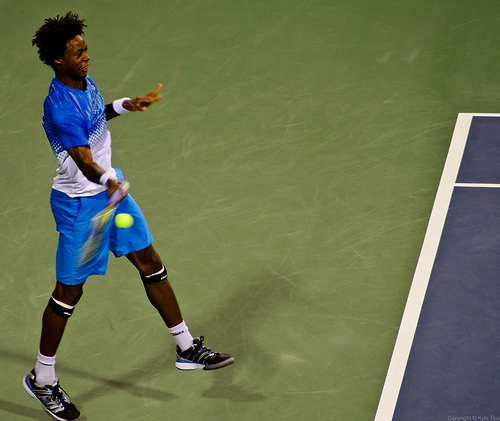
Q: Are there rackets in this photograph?
A: Yes, there is a racket.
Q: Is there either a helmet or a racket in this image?
A: Yes, there is a racket.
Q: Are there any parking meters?
A: No, there are no parking meters.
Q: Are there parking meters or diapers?
A: No, there are no parking meters or diapers.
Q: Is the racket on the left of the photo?
A: Yes, the racket is on the left of the image.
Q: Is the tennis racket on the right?
A: No, the tennis racket is on the left of the image.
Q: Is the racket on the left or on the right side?
A: The racket is on the left of the image.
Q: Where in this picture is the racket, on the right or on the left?
A: The racket is on the left of the image.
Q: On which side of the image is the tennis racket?
A: The tennis racket is on the left of the image.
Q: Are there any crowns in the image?
A: No, there are no crowns.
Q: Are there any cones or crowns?
A: No, there are no crowns or cones.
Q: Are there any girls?
A: No, there are no girls.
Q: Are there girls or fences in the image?
A: No, there are no girls or fences.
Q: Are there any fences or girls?
A: No, there are no girls or fences.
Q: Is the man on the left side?
A: Yes, the man is on the left of the image.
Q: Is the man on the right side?
A: No, the man is on the left of the image.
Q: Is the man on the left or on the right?
A: The man is on the left of the image.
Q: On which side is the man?
A: The man is on the left of the image.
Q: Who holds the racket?
A: The man holds the racket.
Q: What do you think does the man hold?
A: The man holds the tennis racket.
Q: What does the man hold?
A: The man holds the tennis racket.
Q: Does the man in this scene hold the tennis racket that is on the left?
A: Yes, the man holds the tennis racket.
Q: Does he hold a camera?
A: No, the man holds the tennis racket.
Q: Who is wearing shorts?
A: The man is wearing shorts.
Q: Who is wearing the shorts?
A: The man is wearing shorts.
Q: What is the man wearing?
A: The man is wearing shorts.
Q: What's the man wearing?
A: The man is wearing shorts.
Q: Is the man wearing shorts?
A: Yes, the man is wearing shorts.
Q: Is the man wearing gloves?
A: No, the man is wearing shorts.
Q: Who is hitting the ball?
A: The man is hitting the ball.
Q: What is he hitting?
A: The man is hitting the ball.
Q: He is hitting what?
A: The man is hitting the ball.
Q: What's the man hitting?
A: The man is hitting the ball.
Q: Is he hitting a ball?
A: Yes, the man is hitting a ball.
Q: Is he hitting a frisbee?
A: No, the man is hitting a ball.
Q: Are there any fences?
A: No, there are no fences.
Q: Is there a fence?
A: No, there are no fences.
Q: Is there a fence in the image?
A: No, there are no fences.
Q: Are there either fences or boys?
A: No, there are no fences or boys.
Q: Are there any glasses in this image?
A: No, there are no glasses.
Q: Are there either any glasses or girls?
A: No, there are no glasses or girls.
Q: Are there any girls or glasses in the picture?
A: No, there are no glasses or girls.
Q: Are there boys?
A: No, there are no boys.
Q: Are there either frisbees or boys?
A: No, there are no boys or frisbees.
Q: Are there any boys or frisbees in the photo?
A: No, there are no boys or frisbees.